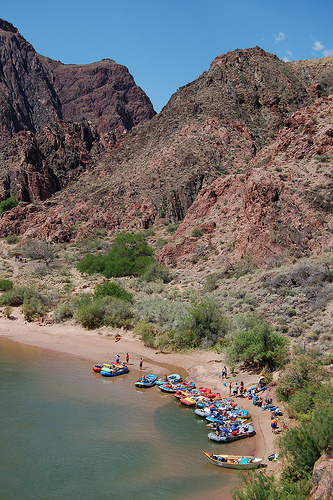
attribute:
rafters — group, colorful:
[88, 330, 294, 470]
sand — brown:
[179, 350, 219, 370]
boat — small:
[202, 445, 263, 468]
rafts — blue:
[161, 365, 262, 458]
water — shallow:
[0, 335, 257, 499]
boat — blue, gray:
[134, 367, 156, 389]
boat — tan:
[200, 451, 264, 470]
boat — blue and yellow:
[98, 362, 127, 377]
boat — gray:
[207, 420, 255, 444]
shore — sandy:
[4, 307, 296, 498]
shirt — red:
[122, 355, 131, 361]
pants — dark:
[134, 361, 145, 367]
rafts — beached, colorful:
[91, 354, 258, 478]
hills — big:
[1, 23, 332, 291]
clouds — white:
[270, 30, 331, 60]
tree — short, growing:
[154, 333, 169, 354]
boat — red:
[203, 449, 264, 470]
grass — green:
[195, 343, 219, 350]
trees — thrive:
[63, 229, 199, 337]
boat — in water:
[134, 373, 158, 387]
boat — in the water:
[135, 0, 159, 20]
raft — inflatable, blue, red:
[135, 373, 158, 387]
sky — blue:
[59, 8, 331, 79]